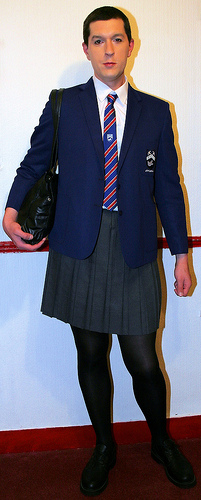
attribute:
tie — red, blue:
[104, 93, 117, 210]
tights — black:
[75, 335, 157, 405]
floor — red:
[7, 458, 187, 498]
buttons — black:
[115, 180, 123, 216]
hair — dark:
[80, 6, 136, 50]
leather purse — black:
[19, 78, 73, 260]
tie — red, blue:
[86, 85, 135, 216]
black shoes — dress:
[73, 422, 198, 495]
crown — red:
[1, 234, 46, 254]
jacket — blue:
[3, 77, 198, 268]